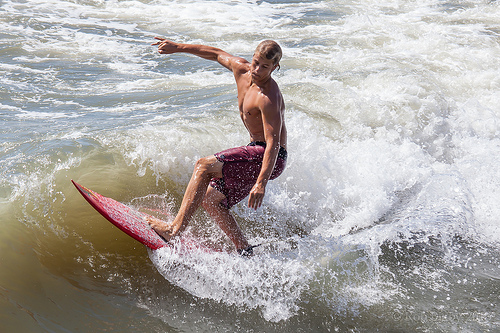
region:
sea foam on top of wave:
[332, 93, 425, 194]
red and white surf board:
[49, 166, 152, 264]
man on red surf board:
[89, 23, 351, 310]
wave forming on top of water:
[0, 136, 72, 319]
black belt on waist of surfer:
[241, 136, 290, 156]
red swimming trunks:
[187, 145, 282, 224]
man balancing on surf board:
[26, 31, 379, 285]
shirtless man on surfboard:
[124, 23, 329, 154]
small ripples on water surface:
[24, 31, 144, 127]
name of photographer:
[374, 289, 499, 328]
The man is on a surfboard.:
[71, 20, 316, 278]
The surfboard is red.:
[66, 171, 271, 284]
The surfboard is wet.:
[64, 167, 259, 291]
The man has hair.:
[239, 28, 291, 93]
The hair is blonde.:
[241, 22, 290, 93]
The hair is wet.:
[243, 20, 290, 98]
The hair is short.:
[243, 25, 295, 87]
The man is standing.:
[129, 11, 298, 287]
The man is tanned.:
[138, 27, 296, 280]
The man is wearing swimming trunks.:
[130, 23, 308, 280]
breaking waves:
[279, 12, 494, 319]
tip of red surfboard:
[67, 165, 149, 277]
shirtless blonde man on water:
[155, 30, 313, 157]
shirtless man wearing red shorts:
[151, 30, 307, 241]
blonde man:
[237, 37, 290, 92]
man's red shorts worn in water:
[212, 130, 310, 222]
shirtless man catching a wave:
[70, 30, 310, 265]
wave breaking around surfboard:
[20, 122, 190, 304]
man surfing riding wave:
[38, 25, 391, 297]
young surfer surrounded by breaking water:
[18, 2, 488, 332]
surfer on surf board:
[147, 32, 297, 265]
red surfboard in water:
[69, 167, 267, 289]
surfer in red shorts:
[203, 62, 301, 230]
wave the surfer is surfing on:
[32, 109, 190, 259]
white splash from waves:
[306, 89, 433, 244]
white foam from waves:
[110, 110, 167, 159]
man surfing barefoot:
[117, 93, 306, 280]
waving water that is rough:
[290, 15, 456, 177]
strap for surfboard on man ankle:
[223, 234, 308, 276]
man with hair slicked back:
[190, 22, 311, 139]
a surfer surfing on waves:
[141, 24, 336, 226]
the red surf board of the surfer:
[69, 149, 167, 284]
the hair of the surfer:
[142, 38, 434, 125]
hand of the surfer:
[131, 25, 176, 77]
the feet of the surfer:
[120, 189, 265, 266]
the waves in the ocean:
[352, 141, 409, 290]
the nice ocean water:
[0, 208, 135, 325]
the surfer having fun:
[125, 6, 445, 238]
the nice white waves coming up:
[331, 86, 436, 225]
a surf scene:
[19, 11, 498, 298]